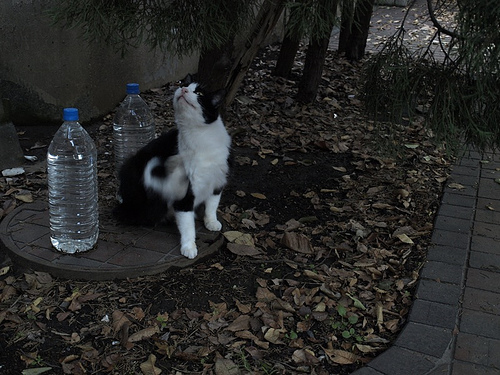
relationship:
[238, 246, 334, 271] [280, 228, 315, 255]
twig lying near leaf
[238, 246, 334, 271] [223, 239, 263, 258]
twig lying near leaf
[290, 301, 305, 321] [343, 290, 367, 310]
twig lying near leaf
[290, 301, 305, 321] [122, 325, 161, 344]
twig lying near leaf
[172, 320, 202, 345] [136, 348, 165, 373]
twig lying near leaf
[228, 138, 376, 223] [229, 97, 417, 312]
dirt on ground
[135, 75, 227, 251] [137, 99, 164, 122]
cat looking up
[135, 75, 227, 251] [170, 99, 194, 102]
cat with nose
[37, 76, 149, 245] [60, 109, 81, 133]
bottle with cap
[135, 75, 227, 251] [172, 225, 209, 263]
cat scratching  with foot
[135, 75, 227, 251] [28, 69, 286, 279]
cat on brick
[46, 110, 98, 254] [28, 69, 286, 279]
water bottle on brick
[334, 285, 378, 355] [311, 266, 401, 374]
clovers are growing on dead leaves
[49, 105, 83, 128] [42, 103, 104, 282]
cap of water bottle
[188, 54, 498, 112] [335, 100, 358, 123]
trees with trunks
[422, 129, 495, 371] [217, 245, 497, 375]
cobblestone of walkway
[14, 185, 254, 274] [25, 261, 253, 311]
man hole cover on ground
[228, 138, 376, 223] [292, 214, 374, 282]
dirt surrounded by leaves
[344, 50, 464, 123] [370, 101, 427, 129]
branches are  hanging down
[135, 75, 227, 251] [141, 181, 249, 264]
cat  sitting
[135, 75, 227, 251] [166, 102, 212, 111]
cat looking up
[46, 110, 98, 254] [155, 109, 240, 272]
water bottle beside cat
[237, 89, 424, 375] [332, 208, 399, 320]
ground covered with leaves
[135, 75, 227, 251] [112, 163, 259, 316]
cat sitting  on something round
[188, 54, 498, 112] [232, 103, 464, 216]
trees in background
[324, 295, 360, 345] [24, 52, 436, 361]
plant grows in ground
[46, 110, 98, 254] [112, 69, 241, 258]
water bottle on side of cat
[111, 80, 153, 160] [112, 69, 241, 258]
water bottle on side of cat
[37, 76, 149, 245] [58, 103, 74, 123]
bottle has top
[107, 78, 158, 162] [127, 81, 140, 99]
bottle has top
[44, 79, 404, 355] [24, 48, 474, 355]
leaves on ground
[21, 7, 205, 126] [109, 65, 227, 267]
rock structure behind cat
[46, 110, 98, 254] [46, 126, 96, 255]
water bottle filled with water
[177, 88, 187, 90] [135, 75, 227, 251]
nose of cat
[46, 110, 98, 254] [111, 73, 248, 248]
water bottle beside cat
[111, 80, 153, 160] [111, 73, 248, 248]
water bottle beside cat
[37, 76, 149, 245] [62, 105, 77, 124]
bottle has cap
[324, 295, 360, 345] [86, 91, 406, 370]
plant grows in leaves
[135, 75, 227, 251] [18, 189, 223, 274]
cat sits on object